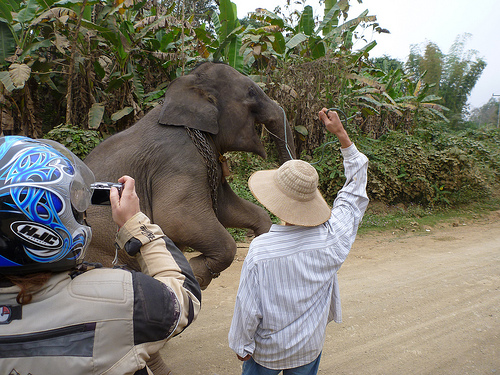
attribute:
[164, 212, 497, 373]
ground — dirt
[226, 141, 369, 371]
shirt — white 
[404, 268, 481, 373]
ground — tan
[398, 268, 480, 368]
ground — dirt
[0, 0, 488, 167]
plants — tall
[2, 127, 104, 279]
helmet — blue 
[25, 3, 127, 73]
leaves — large 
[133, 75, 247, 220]
elephant — brown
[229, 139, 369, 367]
dress shirt — striped, long sleeved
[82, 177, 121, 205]
camera — gray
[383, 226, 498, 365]
road — dirt , long 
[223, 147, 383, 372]
shirt — grey, white, striped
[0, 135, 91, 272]
helmet — black, blue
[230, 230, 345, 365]
shirt — long-sleeve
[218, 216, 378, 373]
shirt — gray , tan 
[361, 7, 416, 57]
clouds — white 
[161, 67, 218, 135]
ear — small